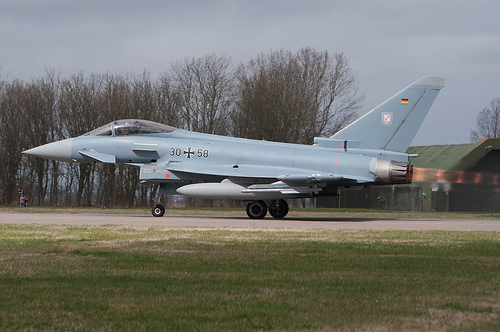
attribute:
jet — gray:
[15, 65, 452, 220]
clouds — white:
[23, 9, 197, 64]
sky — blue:
[5, 7, 491, 132]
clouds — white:
[191, 16, 349, 55]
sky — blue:
[51, 12, 180, 65]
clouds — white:
[0, 0, 497, 145]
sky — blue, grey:
[0, 1, 497, 139]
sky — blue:
[58, 11, 173, 57]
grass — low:
[145, 251, 397, 312]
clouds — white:
[330, 20, 472, 66]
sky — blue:
[75, 15, 449, 95]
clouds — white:
[121, 26, 257, 77]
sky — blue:
[341, 21, 459, 91]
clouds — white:
[297, 26, 425, 90]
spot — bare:
[420, 313, 480, 327]